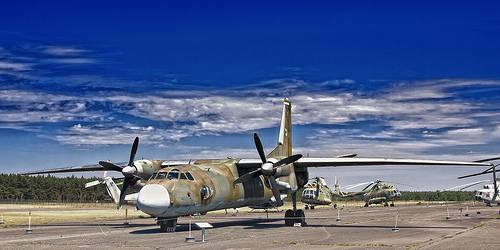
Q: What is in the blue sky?
A: Clouds.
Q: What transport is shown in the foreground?
A: Plane.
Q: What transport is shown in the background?
A: Helicopters.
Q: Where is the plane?
A: The tarmac.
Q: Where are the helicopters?
A: Tarmac.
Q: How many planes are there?
A: One.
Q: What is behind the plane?
A: Helicopters.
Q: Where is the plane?
A: On a landing strip.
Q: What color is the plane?
A: Camouflage.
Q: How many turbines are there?
A: Two.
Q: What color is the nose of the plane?
A: White.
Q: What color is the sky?
A: Blue.